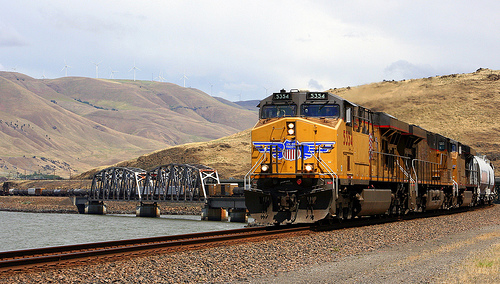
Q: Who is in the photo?
A: No one.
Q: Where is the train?
A: On the tracks.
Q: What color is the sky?
A: Blue.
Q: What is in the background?
A: Hills.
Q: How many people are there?
A: None.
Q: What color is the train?
A: Yellow.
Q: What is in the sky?
A: Clouds.